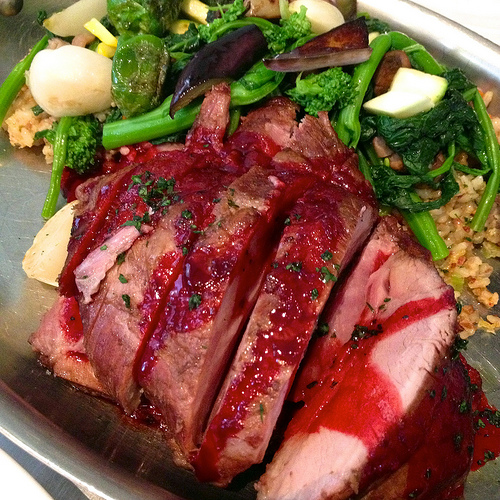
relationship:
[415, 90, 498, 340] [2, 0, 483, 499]
rice served on plate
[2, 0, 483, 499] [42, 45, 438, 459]
plate has food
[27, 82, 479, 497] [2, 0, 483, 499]
meat on plate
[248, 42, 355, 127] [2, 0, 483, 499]
broccoli on plate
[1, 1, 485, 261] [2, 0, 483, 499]
vegetables on plate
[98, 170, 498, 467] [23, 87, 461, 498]
seasoning on meat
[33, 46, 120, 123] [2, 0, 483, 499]
potatoes on plate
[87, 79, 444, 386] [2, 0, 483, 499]
food on plate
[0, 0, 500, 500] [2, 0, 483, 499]
food on plate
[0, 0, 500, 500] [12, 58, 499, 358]
food on plate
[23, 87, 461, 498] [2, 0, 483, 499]
meat on plate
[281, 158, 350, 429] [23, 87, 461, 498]
blood on meat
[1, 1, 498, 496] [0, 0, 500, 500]
bowl with food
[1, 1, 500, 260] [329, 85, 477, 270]
vegetables on rice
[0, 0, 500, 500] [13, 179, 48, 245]
food on plate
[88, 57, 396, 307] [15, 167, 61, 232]
food on plate